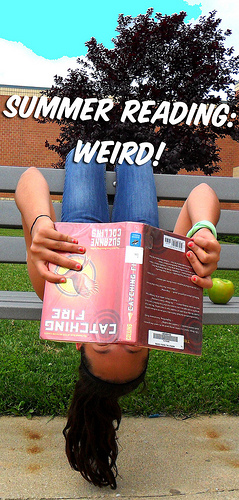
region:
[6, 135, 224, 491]
girl upside down on a bench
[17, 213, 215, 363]
girl is reading a book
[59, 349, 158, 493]
girls long dark ponytail is touching the ground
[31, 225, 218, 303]
girl has painted fingernails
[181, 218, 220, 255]
green band around a girls right wrist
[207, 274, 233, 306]
shiny green apple on a bench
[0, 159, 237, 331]
metal park bench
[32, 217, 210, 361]
reading book has a dust cover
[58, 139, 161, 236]
girl is wearing blue jeans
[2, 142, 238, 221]
girls legs are hanging over the back of a bench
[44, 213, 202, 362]
a hardcover copy of the book "Catching Fire"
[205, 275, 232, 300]
an apple sitting on the bench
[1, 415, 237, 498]
part of a sidewalk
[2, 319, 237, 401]
the grass below the bench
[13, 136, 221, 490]
the girl sitting upside down on the bench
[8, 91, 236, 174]
the writing on the picture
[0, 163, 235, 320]
the bench the woman is sitting on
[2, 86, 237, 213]
the building in the background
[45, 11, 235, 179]
the tree behind the bench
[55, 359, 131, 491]
the girl's hanging from her head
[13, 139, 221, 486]
woman reading a book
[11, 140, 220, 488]
young woman reading a book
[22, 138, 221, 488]
upside down woman reading a book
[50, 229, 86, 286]
well worn manicure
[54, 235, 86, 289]
somewhat short fingernails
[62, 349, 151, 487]
hair hanging upside down and touching the ground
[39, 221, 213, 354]
a hardback copy of "Catching Fire"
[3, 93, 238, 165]
a label for the photo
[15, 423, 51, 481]
rust spots on the sidewalk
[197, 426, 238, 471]
three rust spots on sidewalk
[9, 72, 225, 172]
Summer reading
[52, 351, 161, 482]
Hair from girl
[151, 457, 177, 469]
Sidewalk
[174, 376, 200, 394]
Green grass in front of school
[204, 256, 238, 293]
Apple on the bench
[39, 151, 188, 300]
Girl reading a book upside down on the bench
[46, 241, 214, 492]
Girl reading a book upside down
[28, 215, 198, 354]
Girl holding book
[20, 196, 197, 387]
Reading upside down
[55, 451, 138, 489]
The girl's hair touching the sidewalk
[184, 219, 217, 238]
a green bracelet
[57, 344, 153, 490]
the girl's black hair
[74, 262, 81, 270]
a red fingernail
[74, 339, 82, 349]
the ear of the girl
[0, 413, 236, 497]
a gray cement sidewalk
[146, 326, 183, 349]
a white sticker on the book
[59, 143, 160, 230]
a pair of blue jeans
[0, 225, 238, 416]
a green grassy lawn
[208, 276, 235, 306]
a green apple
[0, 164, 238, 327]
a gray bench